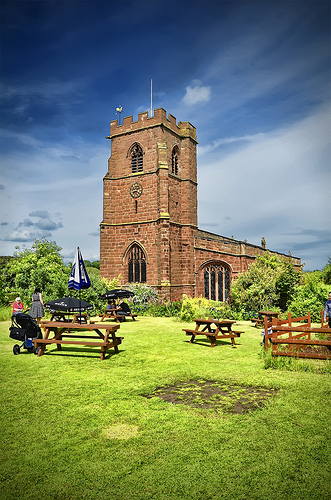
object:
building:
[100, 108, 301, 319]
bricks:
[148, 223, 189, 286]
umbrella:
[68, 246, 91, 290]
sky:
[1, 2, 330, 235]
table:
[35, 322, 123, 360]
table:
[182, 319, 245, 346]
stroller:
[9, 313, 43, 355]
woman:
[13, 297, 23, 316]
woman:
[30, 288, 45, 325]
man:
[324, 292, 330, 329]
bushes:
[0, 238, 65, 293]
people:
[107, 300, 131, 316]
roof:
[110, 108, 196, 142]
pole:
[150, 79, 152, 117]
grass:
[0, 370, 331, 500]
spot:
[104, 423, 138, 440]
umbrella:
[45, 298, 92, 311]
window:
[132, 142, 144, 173]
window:
[128, 240, 147, 282]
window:
[172, 146, 179, 174]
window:
[204, 260, 231, 302]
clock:
[130, 182, 143, 198]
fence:
[264, 312, 330, 359]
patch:
[141, 377, 276, 415]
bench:
[34, 340, 108, 360]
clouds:
[0, 204, 67, 241]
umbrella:
[99, 289, 134, 299]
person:
[119, 300, 131, 315]